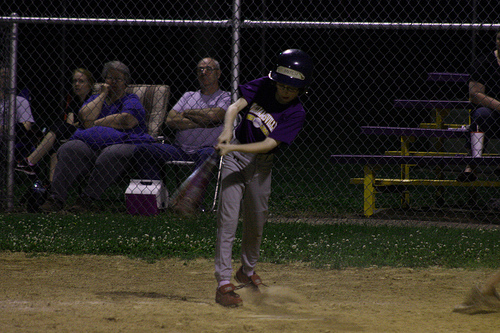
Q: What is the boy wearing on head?
A: A helmet.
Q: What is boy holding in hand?
A: A baseball bat.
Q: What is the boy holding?
A: Bat.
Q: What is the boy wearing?
A: A uniform.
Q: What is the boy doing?
A: Playing baseball.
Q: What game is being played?
A: Baseball.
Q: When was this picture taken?
A: Early evening.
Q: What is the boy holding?
A: A bat.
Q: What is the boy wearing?
A: A uniform.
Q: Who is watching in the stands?
A: Spectators.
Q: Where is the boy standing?
A: The mound.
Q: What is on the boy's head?
A: A helmet.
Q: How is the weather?
A: Clear.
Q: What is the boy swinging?
A: A bat.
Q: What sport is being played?
A: Baseball.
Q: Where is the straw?
A: In cup.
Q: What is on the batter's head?
A: Batting helmet.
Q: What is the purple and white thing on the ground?
A: A cooler.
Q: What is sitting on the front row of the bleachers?
A: Cup.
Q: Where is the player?
A: At home plate.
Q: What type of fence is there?
A: Chain link.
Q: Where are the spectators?
A: Behind the fence.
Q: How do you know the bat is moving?
A: It's blurry.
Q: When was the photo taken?
A: Night time.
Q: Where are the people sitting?
A: Outside the fence.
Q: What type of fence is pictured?
A: Metal.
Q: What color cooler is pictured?
A: Purple and white.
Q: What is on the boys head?
A: Helmet.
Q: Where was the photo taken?
A: At a ballgame.